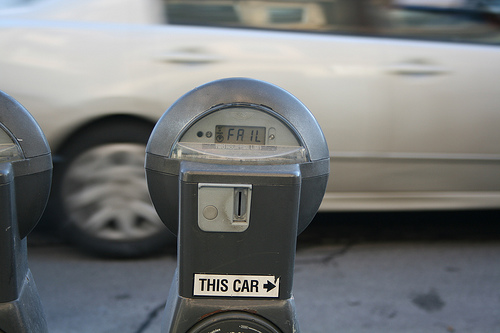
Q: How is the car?
A: In motion.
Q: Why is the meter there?
A: Parking.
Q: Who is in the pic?
A: No one.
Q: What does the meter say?
A: Fail.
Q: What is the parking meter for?
A: Cars.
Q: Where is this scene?
A: City street.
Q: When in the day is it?
A: Daytime.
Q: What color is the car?
A: Off white.